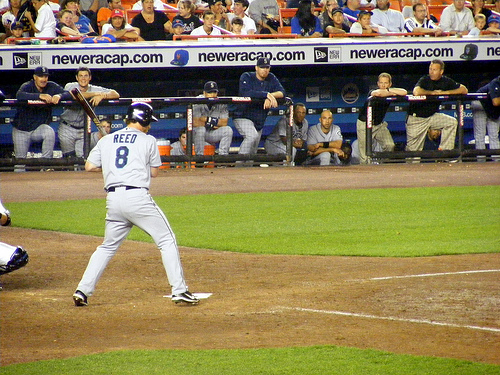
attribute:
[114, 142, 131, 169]
number — 8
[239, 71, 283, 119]
shirt — blue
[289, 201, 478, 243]
grass — short, green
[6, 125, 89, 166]
pants — tan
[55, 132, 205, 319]
uniform — white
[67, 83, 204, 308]
batter — prepping